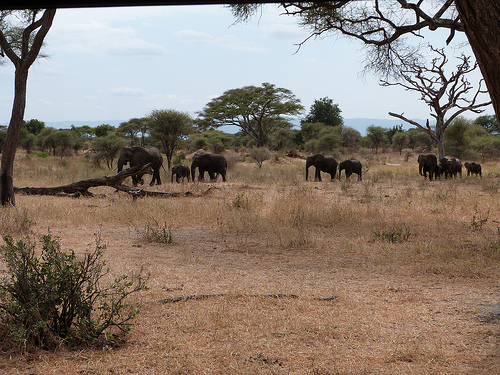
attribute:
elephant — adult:
[112, 144, 168, 190]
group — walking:
[170, 145, 486, 186]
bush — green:
[2, 223, 162, 357]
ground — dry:
[1, 150, 499, 370]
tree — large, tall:
[202, 82, 306, 150]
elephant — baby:
[168, 160, 193, 184]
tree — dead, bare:
[385, 46, 493, 160]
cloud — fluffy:
[58, 9, 164, 64]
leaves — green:
[281, 98, 304, 114]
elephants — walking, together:
[104, 130, 486, 184]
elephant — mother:
[191, 150, 233, 180]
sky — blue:
[3, 11, 490, 128]